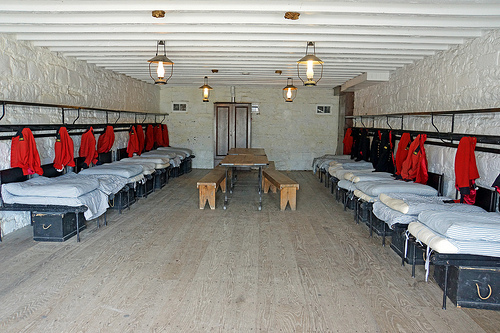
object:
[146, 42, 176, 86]
lamp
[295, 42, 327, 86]
lights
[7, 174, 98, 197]
pillow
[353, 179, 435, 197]
pillow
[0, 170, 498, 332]
floor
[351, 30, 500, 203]
stone walls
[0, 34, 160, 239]
wall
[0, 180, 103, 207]
mattress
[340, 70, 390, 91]
vent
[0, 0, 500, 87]
ceiling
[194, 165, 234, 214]
bench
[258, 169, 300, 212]
bench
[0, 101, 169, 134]
hanger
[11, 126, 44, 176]
clothes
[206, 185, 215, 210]
legs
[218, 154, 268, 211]
table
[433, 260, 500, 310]
trunks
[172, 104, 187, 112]
air conditioning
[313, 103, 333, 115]
air conditioning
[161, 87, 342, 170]
rear wall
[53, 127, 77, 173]
fabric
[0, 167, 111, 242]
beds/walls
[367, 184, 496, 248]
beds/walls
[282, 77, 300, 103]
light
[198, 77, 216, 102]
light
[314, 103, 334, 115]
vent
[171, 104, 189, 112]
vent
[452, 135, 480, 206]
robe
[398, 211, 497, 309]
bed